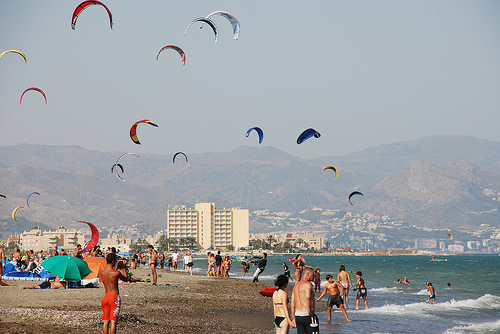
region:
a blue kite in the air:
[281, 111, 330, 155]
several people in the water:
[386, 270, 468, 320]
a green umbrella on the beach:
[30, 247, 98, 310]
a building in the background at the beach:
[147, 187, 276, 287]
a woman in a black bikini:
[265, 270, 292, 331]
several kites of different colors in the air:
[121, 6, 345, 190]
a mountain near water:
[341, 108, 499, 268]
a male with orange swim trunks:
[92, 248, 132, 331]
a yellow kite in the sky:
[0, 40, 32, 68]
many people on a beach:
[129, 238, 241, 295]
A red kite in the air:
[70, 0, 118, 31]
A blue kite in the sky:
[241, 123, 271, 146]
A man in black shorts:
[293, 265, 320, 332]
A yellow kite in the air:
[1, 46, 32, 71]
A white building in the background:
[166, 202, 253, 247]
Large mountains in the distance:
[0, 134, 499, 226]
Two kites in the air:
[181, 1, 239, 47]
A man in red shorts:
[96, 250, 131, 332]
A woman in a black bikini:
[269, 271, 291, 332]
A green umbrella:
[41, 253, 89, 278]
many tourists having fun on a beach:
[4, 241, 348, 331]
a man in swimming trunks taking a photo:
[88, 244, 129, 329]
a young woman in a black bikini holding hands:
[265, 261, 292, 331]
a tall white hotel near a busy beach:
[159, 196, 259, 253]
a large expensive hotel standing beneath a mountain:
[161, 198, 272, 261]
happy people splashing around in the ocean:
[394, 268, 454, 304]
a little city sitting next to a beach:
[260, 231, 342, 251]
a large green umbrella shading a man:
[35, 249, 95, 282]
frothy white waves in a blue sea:
[385, 294, 497, 317]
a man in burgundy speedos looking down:
[144, 245, 160, 286]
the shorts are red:
[96, 293, 131, 315]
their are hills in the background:
[337, 136, 457, 197]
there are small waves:
[368, 290, 496, 327]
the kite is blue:
[243, 117, 332, 149]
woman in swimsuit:
[269, 285, 291, 332]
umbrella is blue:
[51, 250, 93, 276]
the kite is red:
[81, 219, 103, 245]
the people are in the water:
[395, 260, 461, 311]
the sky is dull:
[58, 71, 364, 115]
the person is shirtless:
[94, 272, 130, 286]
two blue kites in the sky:
[232, 115, 327, 161]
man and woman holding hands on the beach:
[252, 260, 325, 332]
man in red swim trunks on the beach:
[84, 247, 128, 332]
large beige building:
[157, 195, 260, 255]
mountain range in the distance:
[0, 134, 499, 215]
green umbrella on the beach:
[35, 250, 95, 301]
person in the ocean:
[407, 279, 453, 316]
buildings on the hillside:
[285, 215, 414, 252]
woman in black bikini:
[269, 267, 290, 332]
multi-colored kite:
[110, 110, 172, 145]